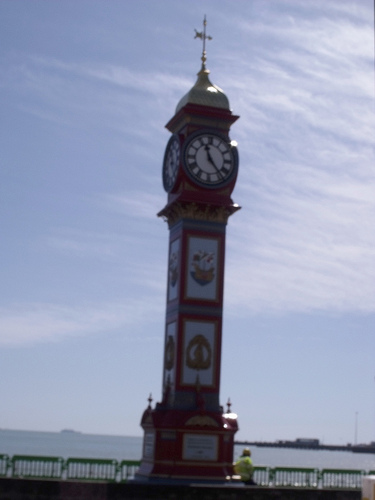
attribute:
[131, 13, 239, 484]
tower — red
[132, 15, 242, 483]
clock tower — skinny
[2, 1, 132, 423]
sky — sunny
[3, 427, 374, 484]
ocean — blue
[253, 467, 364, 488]
barrier — protection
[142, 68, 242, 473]
tower — very tall, clock tower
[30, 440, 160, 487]
fence — metal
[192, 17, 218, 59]
vane — weather vane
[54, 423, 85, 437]
silhouette — ship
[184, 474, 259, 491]
reflection — bright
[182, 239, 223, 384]
decorations — pointed